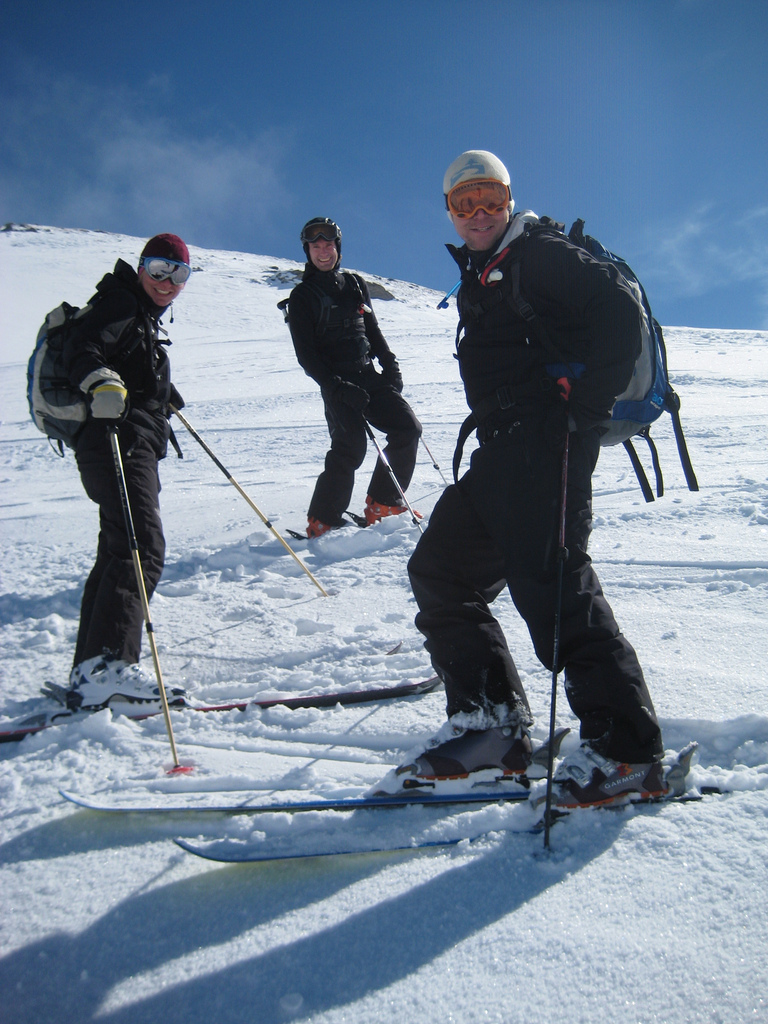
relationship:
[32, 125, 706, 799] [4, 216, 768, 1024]
person on slope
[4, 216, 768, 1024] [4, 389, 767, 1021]
slope covering ground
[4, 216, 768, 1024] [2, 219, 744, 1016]
slope covering ground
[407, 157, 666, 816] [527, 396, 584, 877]
man holding pole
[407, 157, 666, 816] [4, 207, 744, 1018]
man on slope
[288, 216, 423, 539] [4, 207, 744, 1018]
skier on slope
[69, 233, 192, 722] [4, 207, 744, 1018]
man on slope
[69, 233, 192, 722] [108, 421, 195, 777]
man holding poles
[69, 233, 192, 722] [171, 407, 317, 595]
man holding ski pole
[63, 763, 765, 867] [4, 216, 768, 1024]
skis covered with slope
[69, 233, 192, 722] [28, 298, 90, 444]
man with a backpack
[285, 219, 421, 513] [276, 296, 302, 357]
skier with a backpack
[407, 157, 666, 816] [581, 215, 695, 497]
man with a backpack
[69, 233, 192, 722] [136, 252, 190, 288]
man with black goggles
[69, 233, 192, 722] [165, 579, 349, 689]
man on some snow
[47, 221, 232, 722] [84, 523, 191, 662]
man wearing pants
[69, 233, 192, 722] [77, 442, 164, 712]
man wearing pants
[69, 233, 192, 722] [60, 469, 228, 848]
man wearing black pants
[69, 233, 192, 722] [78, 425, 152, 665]
man wearing black pants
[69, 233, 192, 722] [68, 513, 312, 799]
man holding ski poles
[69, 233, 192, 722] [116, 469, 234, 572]
man holding ski poles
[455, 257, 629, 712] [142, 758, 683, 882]
man on skis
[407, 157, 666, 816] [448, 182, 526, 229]
man wearing orange ski goggles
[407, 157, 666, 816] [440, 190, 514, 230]
man wearing orange ski goggles